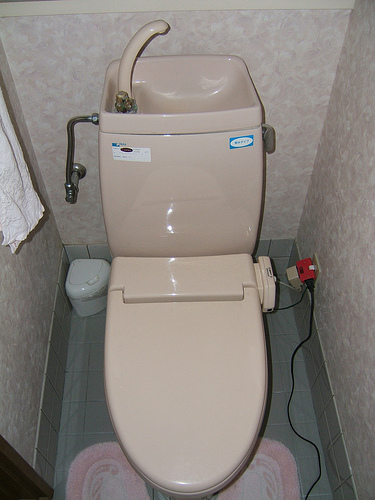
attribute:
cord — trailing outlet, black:
[293, 287, 324, 496]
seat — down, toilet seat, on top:
[104, 252, 267, 498]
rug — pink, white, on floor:
[73, 451, 297, 499]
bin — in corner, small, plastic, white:
[62, 258, 111, 314]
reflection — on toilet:
[160, 206, 185, 238]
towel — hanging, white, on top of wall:
[0, 87, 64, 248]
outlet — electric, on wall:
[306, 251, 324, 285]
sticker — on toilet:
[115, 144, 153, 165]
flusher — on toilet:
[264, 122, 279, 153]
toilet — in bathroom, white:
[78, 19, 285, 496]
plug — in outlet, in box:
[306, 280, 317, 297]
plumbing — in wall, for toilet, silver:
[59, 115, 99, 207]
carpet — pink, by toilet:
[69, 442, 138, 499]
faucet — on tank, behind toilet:
[111, 15, 173, 113]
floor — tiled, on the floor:
[65, 321, 108, 446]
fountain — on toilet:
[100, 14, 263, 125]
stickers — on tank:
[101, 137, 256, 166]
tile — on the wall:
[33, 273, 84, 477]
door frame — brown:
[2, 440, 51, 499]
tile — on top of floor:
[60, 369, 107, 399]